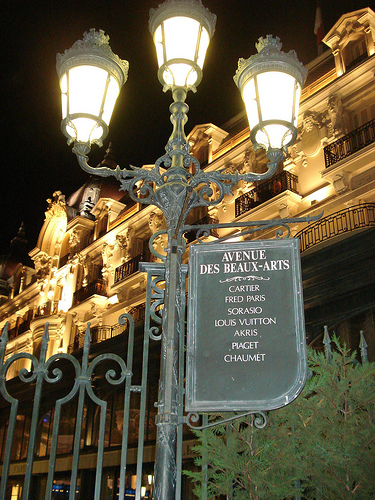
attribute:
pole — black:
[135, 170, 200, 488]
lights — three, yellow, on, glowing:
[43, 5, 304, 165]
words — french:
[200, 255, 291, 366]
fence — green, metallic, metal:
[3, 309, 171, 498]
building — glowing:
[9, 170, 353, 265]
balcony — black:
[62, 257, 149, 317]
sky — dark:
[16, 10, 145, 49]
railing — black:
[225, 181, 296, 211]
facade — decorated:
[29, 195, 126, 313]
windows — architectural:
[27, 189, 119, 267]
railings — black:
[226, 138, 374, 205]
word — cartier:
[224, 281, 265, 298]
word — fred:
[221, 292, 246, 307]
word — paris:
[243, 292, 273, 306]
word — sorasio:
[226, 300, 267, 317]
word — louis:
[211, 314, 240, 331]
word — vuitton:
[238, 311, 279, 329]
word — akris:
[230, 323, 264, 344]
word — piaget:
[230, 334, 267, 351]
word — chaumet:
[222, 347, 274, 371]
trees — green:
[216, 415, 368, 487]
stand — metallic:
[137, 255, 182, 498]